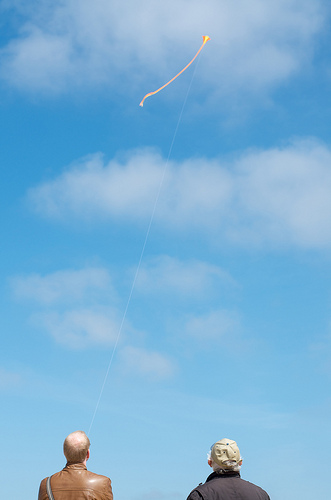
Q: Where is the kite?
A: The sky.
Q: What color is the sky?
A: Blue.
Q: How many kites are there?
A: One.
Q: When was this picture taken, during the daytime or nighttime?
A: Daytime.